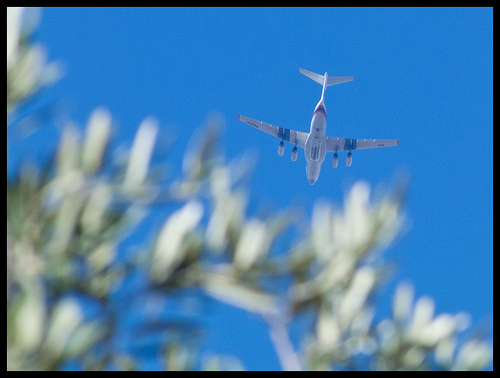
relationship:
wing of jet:
[293, 63, 369, 96] [236, 67, 398, 185]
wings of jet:
[236, 114, 309, 150] [236, 67, 398, 185]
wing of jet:
[326, 137, 403, 155] [236, 67, 398, 185]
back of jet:
[297, 69, 347, 125] [236, 67, 398, 185]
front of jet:
[296, 139, 333, 187] [236, 67, 398, 185]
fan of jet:
[271, 140, 289, 157] [236, 67, 398, 185]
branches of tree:
[253, 326, 322, 377] [29, 147, 470, 372]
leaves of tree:
[27, 185, 123, 246] [29, 147, 470, 372]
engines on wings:
[271, 136, 379, 171] [247, 114, 391, 150]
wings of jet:
[247, 114, 391, 150] [236, 67, 398, 185]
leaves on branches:
[27, 185, 123, 246] [253, 326, 322, 377]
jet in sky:
[236, 67, 398, 185] [15, 13, 479, 367]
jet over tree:
[236, 67, 398, 185] [29, 147, 470, 372]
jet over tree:
[250, 63, 409, 182] [29, 147, 470, 372]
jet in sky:
[250, 63, 409, 182] [15, 13, 479, 367]